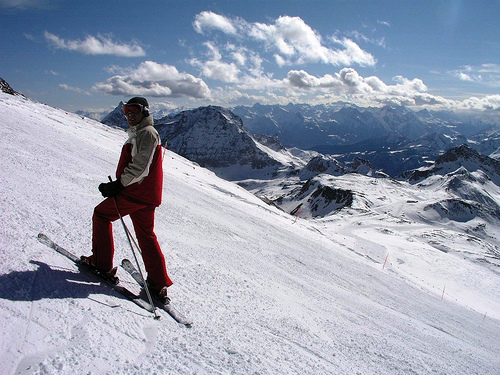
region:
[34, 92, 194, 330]
skier on snowy hill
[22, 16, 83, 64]
white clouds in blue sky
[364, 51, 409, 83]
white clouds in blue sky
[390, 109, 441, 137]
white clouds in blue sky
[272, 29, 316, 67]
white clouds in blue sky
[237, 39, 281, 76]
white clouds in blue sky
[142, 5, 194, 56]
white clouds in blue sky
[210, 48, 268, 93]
white clouds in blue sky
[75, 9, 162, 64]
white clouds in blue sky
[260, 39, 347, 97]
white clouds in blue sky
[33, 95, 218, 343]
The person is skiing.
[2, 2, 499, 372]
Taken on a ski slope.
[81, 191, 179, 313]
The pants are red.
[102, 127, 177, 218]
The jacket is red and white.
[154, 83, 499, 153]
There are mountains in the background.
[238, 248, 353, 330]
Snow on the ground.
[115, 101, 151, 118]
The skier is wearing goggles.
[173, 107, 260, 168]
There is snow on the mountains.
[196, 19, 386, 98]
Clouds in the sky.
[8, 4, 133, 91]
The sky is blue.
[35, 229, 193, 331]
Man on skis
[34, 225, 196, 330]
Man is on skis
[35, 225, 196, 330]
Man is on the snow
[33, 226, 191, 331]
Man is wearing skis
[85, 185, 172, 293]
Man wearing pants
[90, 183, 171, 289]
Man is wearing pants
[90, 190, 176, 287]
Man wearing red pants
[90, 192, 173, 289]
Man is wearing red pants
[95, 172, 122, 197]
Man wearing black gloves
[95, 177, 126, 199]
Man is wearing black gloves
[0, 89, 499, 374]
a steep ski slope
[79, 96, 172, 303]
a man skiing on the slope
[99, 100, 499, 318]
a nearby group of mountains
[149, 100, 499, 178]
a mountainous terrain in the background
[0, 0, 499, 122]
a large area of blue cloudy sky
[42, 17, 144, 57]
a cloud in the sky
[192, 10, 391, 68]
a group of clouds in the sky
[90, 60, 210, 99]
a group of clouds in the sky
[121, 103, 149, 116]
the man's ski goggles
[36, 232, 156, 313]
the man's left ski